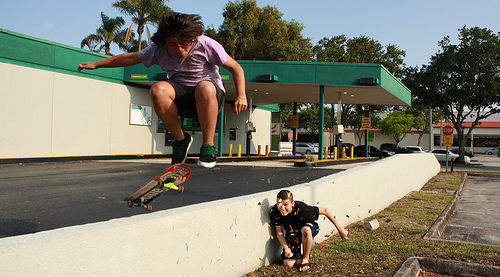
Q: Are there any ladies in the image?
A: No, there are no ladies.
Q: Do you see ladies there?
A: No, there are no ladies.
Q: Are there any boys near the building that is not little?
A: Yes, there is a boy near the building.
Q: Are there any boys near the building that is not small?
A: Yes, there is a boy near the building.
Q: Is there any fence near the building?
A: No, there is a boy near the building.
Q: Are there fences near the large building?
A: No, there is a boy near the building.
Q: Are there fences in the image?
A: No, there are no fences.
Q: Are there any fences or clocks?
A: No, there are no fences or clocks.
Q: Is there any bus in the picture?
A: No, there are no buses.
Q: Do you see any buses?
A: No, there are no buses.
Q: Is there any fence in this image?
A: No, there are no fences.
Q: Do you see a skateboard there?
A: Yes, there is a skateboard.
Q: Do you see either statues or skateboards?
A: Yes, there is a skateboard.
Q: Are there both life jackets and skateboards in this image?
A: No, there is a skateboard but no life jackets.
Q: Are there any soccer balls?
A: No, there are no soccer balls.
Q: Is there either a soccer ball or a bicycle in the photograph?
A: No, there are no soccer balls or bicycles.